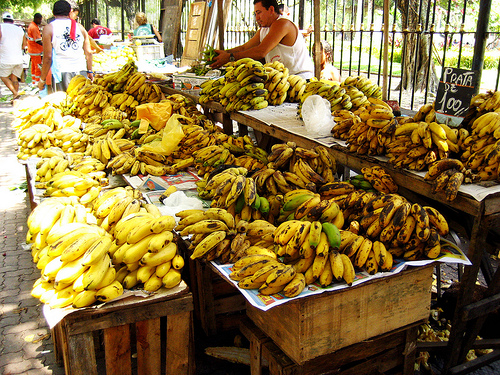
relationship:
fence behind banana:
[177, 0, 498, 112] [370, 105, 395, 120]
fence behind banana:
[177, 0, 498, 112] [275, 67, 290, 93]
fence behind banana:
[177, 0, 498, 112] [345, 72, 356, 85]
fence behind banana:
[177, 0, 498, 112] [248, 93, 264, 105]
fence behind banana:
[177, 0, 498, 112] [391, 122, 421, 135]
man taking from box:
[207, 0, 315, 83] [165, 55, 212, 87]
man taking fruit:
[207, 0, 315, 83] [202, 47, 215, 67]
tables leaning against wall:
[181, 0, 210, 66] [158, 0, 235, 65]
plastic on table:
[303, 100, 326, 132] [245, 79, 350, 156]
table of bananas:
[20, 151, 200, 373] [19, 98, 176, 302]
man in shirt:
[25, 15, 49, 101] [248, 17, 342, 79]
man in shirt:
[0, 12, 27, 102] [1, 21, 25, 66]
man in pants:
[0, 12, 27, 102] [1, 61, 25, 78]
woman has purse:
[128, 4, 157, 49] [150, 23, 171, 55]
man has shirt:
[84, 18, 113, 38] [87, 23, 113, 38]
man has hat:
[84, 18, 113, 38] [89, 17, 107, 27]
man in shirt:
[207, 0, 315, 83] [250, 24, 336, 84]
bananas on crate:
[13, 48, 494, 314] [228, 261, 440, 363]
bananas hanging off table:
[419, 157, 478, 207] [159, 55, 498, 217]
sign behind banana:
[434, 65, 475, 129] [174, 208, 204, 214]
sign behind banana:
[434, 65, 475, 129] [171, 157, 196, 169]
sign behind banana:
[434, 65, 475, 129] [274, 147, 292, 165]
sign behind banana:
[434, 65, 475, 129] [392, 120, 418, 136]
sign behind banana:
[434, 65, 475, 129] [427, 119, 447, 142]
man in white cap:
[0, 12, 27, 102] [0, 12, 17, 21]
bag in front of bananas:
[297, 90, 334, 140] [289, 71, 385, 132]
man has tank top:
[38, 3, 103, 88] [44, 17, 92, 75]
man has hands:
[210, 0, 318, 82] [204, 45, 231, 69]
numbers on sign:
[442, 56, 468, 121] [425, 52, 491, 136]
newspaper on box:
[164, 135, 436, 355] [228, 265, 435, 339]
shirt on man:
[257, 17, 317, 85] [210, 0, 318, 82]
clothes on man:
[27, 22, 41, 81] [27, 13, 43, 83]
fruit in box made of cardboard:
[177, 56, 217, 83] [176, 69, 221, 89]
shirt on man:
[21, 24, 78, 84] [74, 10, 131, 40]